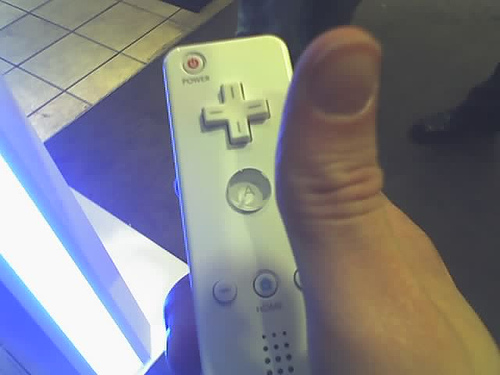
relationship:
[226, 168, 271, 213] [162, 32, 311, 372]
button of remote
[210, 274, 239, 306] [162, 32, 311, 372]
button of remote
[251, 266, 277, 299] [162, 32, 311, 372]
button of remote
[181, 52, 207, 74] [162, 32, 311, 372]
button of remote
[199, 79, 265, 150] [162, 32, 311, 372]
button of remote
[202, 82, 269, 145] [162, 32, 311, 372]
button of remote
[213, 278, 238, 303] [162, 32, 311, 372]
button of remote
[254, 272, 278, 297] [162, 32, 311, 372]
button of remote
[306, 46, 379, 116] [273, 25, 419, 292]
nail of finger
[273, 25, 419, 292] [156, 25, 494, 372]
finger on hand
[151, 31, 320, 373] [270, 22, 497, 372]
controller in hand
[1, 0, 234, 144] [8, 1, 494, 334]
tile on ground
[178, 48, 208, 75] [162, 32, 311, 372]
button on remote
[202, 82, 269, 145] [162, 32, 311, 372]
button on remote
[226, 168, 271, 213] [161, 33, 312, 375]
button on controller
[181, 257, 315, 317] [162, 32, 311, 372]
button on remote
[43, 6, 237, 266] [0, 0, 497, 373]
carpet on ground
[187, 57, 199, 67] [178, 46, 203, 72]
symbol on button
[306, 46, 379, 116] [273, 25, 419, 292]
nail attached to finger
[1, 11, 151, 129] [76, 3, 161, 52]
tile next to tile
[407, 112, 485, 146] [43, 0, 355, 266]
foot on top of a carpet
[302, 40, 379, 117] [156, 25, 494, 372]
nail of a hand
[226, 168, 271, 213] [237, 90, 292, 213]
button on controller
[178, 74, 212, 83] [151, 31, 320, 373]
word on controller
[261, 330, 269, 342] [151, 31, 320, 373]
dot on controller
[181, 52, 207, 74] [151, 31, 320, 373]
button for turning on controller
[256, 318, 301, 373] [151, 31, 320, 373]
speaker on controller